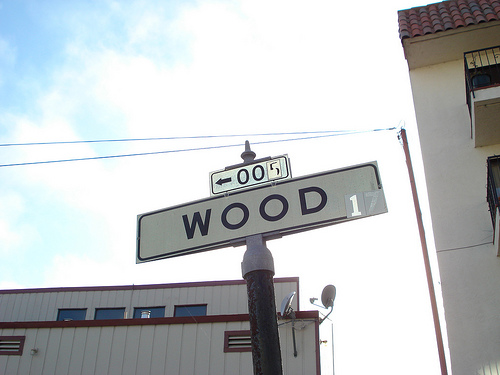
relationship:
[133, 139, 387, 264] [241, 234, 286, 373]
sign on pole